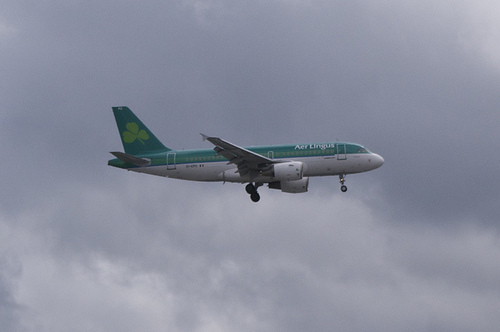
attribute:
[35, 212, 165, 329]
clouds — fluffy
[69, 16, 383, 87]
sky — grey, cloudy, blue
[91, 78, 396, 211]
plane — green, flying, white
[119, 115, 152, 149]
clover — green